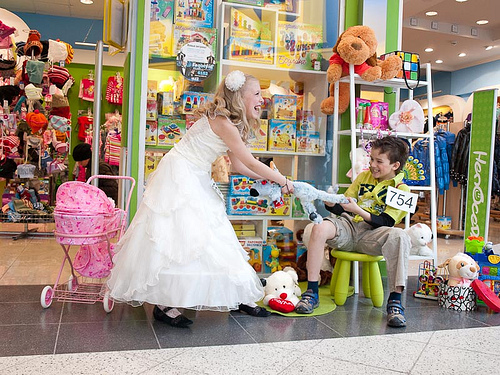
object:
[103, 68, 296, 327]
girl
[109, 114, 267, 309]
dress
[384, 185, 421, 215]
number 754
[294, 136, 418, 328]
boy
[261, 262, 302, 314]
bear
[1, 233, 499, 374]
floor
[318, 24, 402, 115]
stuffed animal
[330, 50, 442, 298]
shelf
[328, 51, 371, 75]
shirt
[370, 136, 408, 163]
hair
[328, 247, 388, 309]
stool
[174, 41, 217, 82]
sign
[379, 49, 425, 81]
rubix cube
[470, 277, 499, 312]
lid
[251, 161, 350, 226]
toy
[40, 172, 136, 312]
toy stroller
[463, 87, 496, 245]
sign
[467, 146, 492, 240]
letters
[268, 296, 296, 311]
heart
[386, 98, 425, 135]
box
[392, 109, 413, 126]
flower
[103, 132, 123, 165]
shirt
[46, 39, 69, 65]
hat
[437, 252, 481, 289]
toy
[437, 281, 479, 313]
hat box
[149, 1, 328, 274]
toys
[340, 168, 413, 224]
shirt